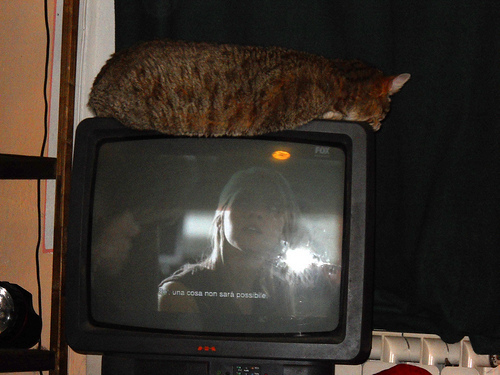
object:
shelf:
[0, 153, 59, 180]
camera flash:
[273, 242, 330, 280]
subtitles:
[156, 285, 266, 301]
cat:
[86, 43, 411, 140]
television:
[60, 118, 367, 374]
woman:
[155, 168, 298, 334]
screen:
[88, 138, 346, 336]